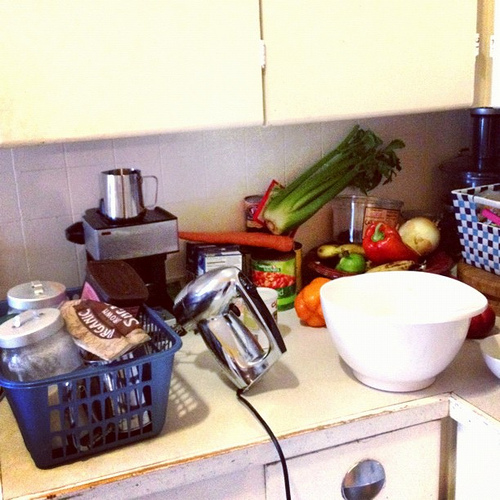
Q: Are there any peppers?
A: Yes, there is a pepper.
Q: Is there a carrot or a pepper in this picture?
A: Yes, there is a pepper.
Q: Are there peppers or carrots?
A: Yes, there is a pepper.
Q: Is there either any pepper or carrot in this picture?
A: Yes, there is a pepper.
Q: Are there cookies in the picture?
A: No, there are no cookies.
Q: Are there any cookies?
A: No, there are no cookies.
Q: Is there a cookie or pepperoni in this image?
A: No, there are no cookies or pepperoni.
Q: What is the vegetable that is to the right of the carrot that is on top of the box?
A: The vegetable is a pepper.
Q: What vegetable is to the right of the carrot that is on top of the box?
A: The vegetable is a pepper.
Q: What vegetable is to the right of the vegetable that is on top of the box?
A: The vegetable is a pepper.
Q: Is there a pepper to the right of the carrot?
A: Yes, there is a pepper to the right of the carrot.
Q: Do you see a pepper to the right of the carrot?
A: Yes, there is a pepper to the right of the carrot.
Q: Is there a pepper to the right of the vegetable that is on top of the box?
A: Yes, there is a pepper to the right of the carrot.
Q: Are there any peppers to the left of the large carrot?
A: No, the pepper is to the right of the carrot.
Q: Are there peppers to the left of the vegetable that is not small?
A: No, the pepper is to the right of the carrot.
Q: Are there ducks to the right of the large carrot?
A: No, there is a pepper to the right of the carrot.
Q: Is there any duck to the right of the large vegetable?
A: No, there is a pepper to the right of the carrot.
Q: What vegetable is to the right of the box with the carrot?
A: The vegetable is a pepper.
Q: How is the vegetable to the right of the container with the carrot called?
A: The vegetable is a pepper.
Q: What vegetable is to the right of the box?
A: The vegetable is a pepper.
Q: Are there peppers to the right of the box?
A: Yes, there is a pepper to the right of the box.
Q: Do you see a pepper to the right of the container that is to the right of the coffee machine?
A: Yes, there is a pepper to the right of the box.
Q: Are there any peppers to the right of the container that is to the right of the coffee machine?
A: Yes, there is a pepper to the right of the box.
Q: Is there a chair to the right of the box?
A: No, there is a pepper to the right of the box.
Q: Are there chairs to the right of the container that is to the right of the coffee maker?
A: No, there is a pepper to the right of the box.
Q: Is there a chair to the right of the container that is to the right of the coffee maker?
A: No, there is a pepper to the right of the box.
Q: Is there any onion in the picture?
A: Yes, there is an onion.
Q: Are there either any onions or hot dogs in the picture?
A: Yes, there is an onion.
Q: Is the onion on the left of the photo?
A: No, the onion is on the right of the image.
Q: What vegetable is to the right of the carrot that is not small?
A: The vegetable is an onion.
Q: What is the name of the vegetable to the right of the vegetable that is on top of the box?
A: The vegetable is an onion.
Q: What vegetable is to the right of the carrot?
A: The vegetable is an onion.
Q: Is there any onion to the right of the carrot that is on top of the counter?
A: Yes, there is an onion to the right of the carrot.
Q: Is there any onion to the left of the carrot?
A: No, the onion is to the right of the carrot.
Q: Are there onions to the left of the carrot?
A: No, the onion is to the right of the carrot.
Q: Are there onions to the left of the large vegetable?
A: No, the onion is to the right of the carrot.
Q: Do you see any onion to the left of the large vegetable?
A: No, the onion is to the right of the carrot.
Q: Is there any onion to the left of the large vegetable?
A: No, the onion is to the right of the carrot.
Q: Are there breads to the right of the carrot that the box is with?
A: No, there is an onion to the right of the carrot.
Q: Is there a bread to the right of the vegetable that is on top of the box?
A: No, there is an onion to the right of the carrot.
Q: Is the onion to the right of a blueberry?
A: No, the onion is to the right of the carrot.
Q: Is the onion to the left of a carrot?
A: No, the onion is to the right of a carrot.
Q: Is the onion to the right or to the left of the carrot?
A: The onion is to the right of the carrot.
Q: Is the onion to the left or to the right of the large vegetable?
A: The onion is to the right of the carrot.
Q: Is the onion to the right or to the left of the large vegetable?
A: The onion is to the right of the carrot.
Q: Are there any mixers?
A: Yes, there is a mixer.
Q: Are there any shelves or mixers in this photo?
A: Yes, there is a mixer.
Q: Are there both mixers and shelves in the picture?
A: No, there is a mixer but no shelves.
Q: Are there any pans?
A: No, there are no pans.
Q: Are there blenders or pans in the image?
A: No, there are no pans or blenders.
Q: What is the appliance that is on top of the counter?
A: The appliance is a mixer.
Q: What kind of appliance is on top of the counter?
A: The appliance is a mixer.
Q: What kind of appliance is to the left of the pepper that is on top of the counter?
A: The appliance is a mixer.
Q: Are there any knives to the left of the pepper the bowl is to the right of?
A: No, there is a mixer to the left of the pepper.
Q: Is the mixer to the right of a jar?
A: Yes, the mixer is to the right of a jar.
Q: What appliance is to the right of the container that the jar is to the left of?
A: The appliance is a mixer.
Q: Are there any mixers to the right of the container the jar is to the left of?
A: Yes, there is a mixer to the right of the container.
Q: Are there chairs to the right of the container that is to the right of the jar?
A: No, there is a mixer to the right of the container.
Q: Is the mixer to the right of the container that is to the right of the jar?
A: Yes, the mixer is to the right of the container.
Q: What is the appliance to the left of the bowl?
A: The appliance is a mixer.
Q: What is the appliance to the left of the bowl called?
A: The appliance is a mixer.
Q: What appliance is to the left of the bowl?
A: The appliance is a mixer.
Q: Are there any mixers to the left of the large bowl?
A: Yes, there is a mixer to the left of the bowl.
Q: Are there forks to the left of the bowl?
A: No, there is a mixer to the left of the bowl.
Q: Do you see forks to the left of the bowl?
A: No, there is a mixer to the left of the bowl.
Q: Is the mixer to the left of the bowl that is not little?
A: Yes, the mixer is to the left of the bowl.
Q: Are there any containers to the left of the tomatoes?
A: Yes, there is a container to the left of the tomatoes.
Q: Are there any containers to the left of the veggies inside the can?
A: Yes, there is a container to the left of the tomatoes.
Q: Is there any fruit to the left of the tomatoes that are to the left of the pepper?
A: No, there is a container to the left of the tomatoes.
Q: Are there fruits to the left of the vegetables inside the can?
A: No, there is a container to the left of the tomatoes.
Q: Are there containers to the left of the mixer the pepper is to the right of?
A: Yes, there is a container to the left of the mixer.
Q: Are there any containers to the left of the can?
A: Yes, there is a container to the left of the can.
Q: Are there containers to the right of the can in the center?
A: No, the container is to the left of the can.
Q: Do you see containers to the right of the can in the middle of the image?
A: No, the container is to the left of the can.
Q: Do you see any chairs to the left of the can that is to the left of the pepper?
A: No, there is a container to the left of the can.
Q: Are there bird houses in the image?
A: No, there are no bird houses.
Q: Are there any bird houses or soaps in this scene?
A: No, there are no bird houses or soaps.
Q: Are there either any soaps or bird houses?
A: No, there are no bird houses or soaps.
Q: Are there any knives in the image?
A: No, there are no knives.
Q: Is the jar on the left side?
A: Yes, the jar is on the left of the image.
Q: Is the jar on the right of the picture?
A: No, the jar is on the left of the image.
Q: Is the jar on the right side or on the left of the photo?
A: The jar is on the left of the image.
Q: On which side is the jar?
A: The jar is on the left of the image.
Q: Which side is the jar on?
A: The jar is on the left of the image.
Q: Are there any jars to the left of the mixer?
A: Yes, there is a jar to the left of the mixer.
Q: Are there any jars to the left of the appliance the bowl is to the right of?
A: Yes, there is a jar to the left of the mixer.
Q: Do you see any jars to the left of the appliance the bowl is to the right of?
A: Yes, there is a jar to the left of the mixer.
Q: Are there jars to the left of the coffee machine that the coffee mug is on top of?
A: Yes, there is a jar to the left of the coffee machine.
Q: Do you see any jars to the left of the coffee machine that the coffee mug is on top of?
A: Yes, there is a jar to the left of the coffee machine.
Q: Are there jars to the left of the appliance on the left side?
A: Yes, there is a jar to the left of the coffee machine.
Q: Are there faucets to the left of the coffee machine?
A: No, there is a jar to the left of the coffee machine.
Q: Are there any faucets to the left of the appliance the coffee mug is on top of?
A: No, there is a jar to the left of the coffee machine.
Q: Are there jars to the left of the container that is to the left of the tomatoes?
A: Yes, there is a jar to the left of the container.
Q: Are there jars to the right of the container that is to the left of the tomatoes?
A: No, the jar is to the left of the container.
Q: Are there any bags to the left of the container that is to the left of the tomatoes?
A: No, there is a jar to the left of the container.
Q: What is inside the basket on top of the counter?
A: The jar is inside the basket.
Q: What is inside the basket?
A: The jar is inside the basket.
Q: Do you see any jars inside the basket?
A: Yes, there is a jar inside the basket.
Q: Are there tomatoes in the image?
A: Yes, there are tomatoes.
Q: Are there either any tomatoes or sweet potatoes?
A: Yes, there are tomatoes.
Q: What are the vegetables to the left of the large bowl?
A: The vegetables are tomatoes.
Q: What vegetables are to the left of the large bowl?
A: The vegetables are tomatoes.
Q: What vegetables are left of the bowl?
A: The vegetables are tomatoes.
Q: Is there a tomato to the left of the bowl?
A: Yes, there are tomatoes to the left of the bowl.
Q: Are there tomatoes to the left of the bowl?
A: Yes, there are tomatoes to the left of the bowl.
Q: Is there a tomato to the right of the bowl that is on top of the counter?
A: No, the tomatoes are to the left of the bowl.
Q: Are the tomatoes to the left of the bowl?
A: Yes, the tomatoes are to the left of the bowl.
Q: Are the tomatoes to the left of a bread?
A: No, the tomatoes are to the left of the bowl.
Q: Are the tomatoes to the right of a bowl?
A: No, the tomatoes are to the left of a bowl.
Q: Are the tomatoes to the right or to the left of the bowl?
A: The tomatoes are to the left of the bowl.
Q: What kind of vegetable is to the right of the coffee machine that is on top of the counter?
A: The vegetables are tomatoes.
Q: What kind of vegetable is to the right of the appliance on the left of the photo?
A: The vegetables are tomatoes.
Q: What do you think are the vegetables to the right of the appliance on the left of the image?
A: The vegetables are tomatoes.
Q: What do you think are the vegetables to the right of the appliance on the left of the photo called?
A: The vegetables are tomatoes.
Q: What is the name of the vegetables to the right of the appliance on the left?
A: The vegetables are tomatoes.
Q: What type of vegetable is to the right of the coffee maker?
A: The vegetables are tomatoes.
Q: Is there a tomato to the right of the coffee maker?
A: Yes, there are tomatoes to the right of the coffee maker.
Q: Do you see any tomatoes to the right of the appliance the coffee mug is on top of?
A: Yes, there are tomatoes to the right of the coffee maker.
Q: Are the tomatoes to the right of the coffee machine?
A: Yes, the tomatoes are to the right of the coffee machine.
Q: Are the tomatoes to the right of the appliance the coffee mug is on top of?
A: Yes, the tomatoes are to the right of the coffee machine.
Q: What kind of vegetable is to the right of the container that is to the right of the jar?
A: The vegetables are tomatoes.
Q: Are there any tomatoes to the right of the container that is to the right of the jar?
A: Yes, there are tomatoes to the right of the container.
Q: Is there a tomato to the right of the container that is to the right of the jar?
A: Yes, there are tomatoes to the right of the container.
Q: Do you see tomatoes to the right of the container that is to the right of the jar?
A: Yes, there are tomatoes to the right of the container.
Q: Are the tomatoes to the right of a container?
A: Yes, the tomatoes are to the right of a container.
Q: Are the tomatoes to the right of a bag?
A: No, the tomatoes are to the right of a container.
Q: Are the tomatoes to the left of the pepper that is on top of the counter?
A: Yes, the tomatoes are to the left of the pepper.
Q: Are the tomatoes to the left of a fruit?
A: No, the tomatoes are to the left of the pepper.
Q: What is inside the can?
A: The tomatoes are inside the can.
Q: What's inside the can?
A: The tomatoes are inside the can.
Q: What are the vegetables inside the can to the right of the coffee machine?
A: The vegetables are tomatoes.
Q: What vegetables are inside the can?
A: The vegetables are tomatoes.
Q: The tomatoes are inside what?
A: The tomatoes are inside the can.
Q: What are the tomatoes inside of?
A: The tomatoes are inside the can.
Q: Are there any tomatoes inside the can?
A: Yes, there are tomatoes inside the can.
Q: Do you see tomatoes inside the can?
A: Yes, there are tomatoes inside the can.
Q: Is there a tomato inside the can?
A: Yes, there are tomatoes inside the can.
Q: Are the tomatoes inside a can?
A: Yes, the tomatoes are inside a can.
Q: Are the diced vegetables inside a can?
A: Yes, the tomatoes are inside a can.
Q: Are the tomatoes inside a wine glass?
A: No, the tomatoes are inside a can.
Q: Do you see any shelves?
A: No, there are no shelves.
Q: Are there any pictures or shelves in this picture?
A: No, there are no shelves or pictures.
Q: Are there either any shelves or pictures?
A: No, there are no shelves or pictures.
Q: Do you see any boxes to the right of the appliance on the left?
A: Yes, there is a box to the right of the coffee maker.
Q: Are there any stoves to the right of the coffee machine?
A: No, there is a box to the right of the coffee machine.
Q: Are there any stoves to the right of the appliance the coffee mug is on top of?
A: No, there is a box to the right of the coffee machine.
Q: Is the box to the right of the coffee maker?
A: Yes, the box is to the right of the coffee maker.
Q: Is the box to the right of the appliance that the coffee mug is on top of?
A: Yes, the box is to the right of the coffee maker.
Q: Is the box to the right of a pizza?
A: No, the box is to the right of the coffee maker.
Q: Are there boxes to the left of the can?
A: Yes, there is a box to the left of the can.